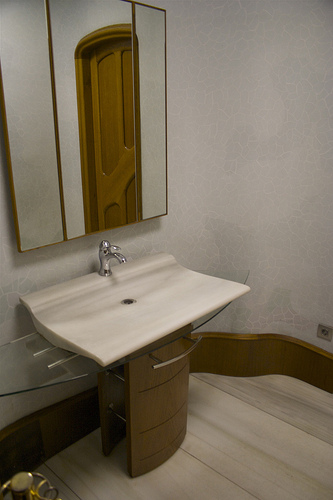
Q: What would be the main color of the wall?
A: White.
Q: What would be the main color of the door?
A: Brown.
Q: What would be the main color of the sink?
A: White.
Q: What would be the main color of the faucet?
A: Silver.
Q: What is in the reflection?
A: Door.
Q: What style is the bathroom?
A: Modern.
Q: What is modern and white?
A: Sink.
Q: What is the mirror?
A: Large.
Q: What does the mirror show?
A: Door.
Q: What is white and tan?
A: Vanity.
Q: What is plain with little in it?
A: Bathroom.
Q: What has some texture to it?
A: The wall.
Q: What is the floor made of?
A: Wood.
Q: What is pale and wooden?
A: Floor.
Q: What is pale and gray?
A: Wallpaper.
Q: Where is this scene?
A: Bathroom.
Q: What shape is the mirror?
A: Rectangular.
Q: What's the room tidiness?
A: Very tidy.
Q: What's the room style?
A: Modern.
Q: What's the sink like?
A: Flat.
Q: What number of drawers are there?
A: 3.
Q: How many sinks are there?
A: One.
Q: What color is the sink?
A: White.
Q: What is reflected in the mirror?
A: A door.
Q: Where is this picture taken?
A: Bathroom.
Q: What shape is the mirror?
A: Square.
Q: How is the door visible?
A: The mirror.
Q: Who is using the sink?
A: No one.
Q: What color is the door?
A: Brown.